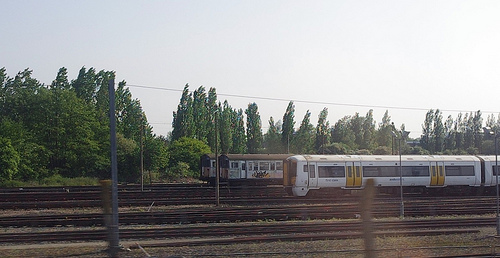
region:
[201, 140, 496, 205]
three trains on the tracks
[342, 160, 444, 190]
yellow doors on the train cars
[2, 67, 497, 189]
trees behind the train tracks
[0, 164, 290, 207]
tracks the trains are on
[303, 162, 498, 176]
windows on the side of white and yellow train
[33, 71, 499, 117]
wire running above the trains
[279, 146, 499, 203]
this is a train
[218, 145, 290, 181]
this is a train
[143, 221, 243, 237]
this is a railway line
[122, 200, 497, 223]
this is a railway line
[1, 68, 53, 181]
this is green vegetation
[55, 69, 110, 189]
this is green vegetation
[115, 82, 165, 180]
this is green vegetation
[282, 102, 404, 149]
this is green vegetation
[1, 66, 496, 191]
The trees lining the track line.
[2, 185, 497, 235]
The tracks the trains are traveling on.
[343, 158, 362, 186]
The first set of yellow doors on the train.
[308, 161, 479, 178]
The passenger windows of the train with the yellow doors.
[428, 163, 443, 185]
The second set of yellow double doors on the train.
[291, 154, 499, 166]
The roof of the train with yellow doors.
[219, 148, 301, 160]
The brown roof of the train in the middle.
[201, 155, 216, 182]
The front of the train on the far left.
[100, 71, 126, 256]
The tall pole in the train yard.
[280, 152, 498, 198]
white train with yellow doors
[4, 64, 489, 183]
trees behind the trains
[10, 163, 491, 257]
several sets of train tracks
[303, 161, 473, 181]
windows on the side of the train car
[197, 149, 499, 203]
three trains on tracks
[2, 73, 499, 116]
power line running above the train tracks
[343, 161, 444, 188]
double doors on the train car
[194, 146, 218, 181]
train car in the background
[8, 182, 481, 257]
gravel around the train tracks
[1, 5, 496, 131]
blue and white sky above the trees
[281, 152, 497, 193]
a white train with yellow doors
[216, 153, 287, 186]
a white train with yellow doors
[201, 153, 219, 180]
a white train with yellow doors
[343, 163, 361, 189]
yellow doors of a train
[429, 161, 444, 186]
yellow doors of a train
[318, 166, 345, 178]
a train's passenger window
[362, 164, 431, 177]
a train's passenger window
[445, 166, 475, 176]
a train's passenger window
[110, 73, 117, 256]
a grey metal pole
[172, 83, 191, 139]
top of a large pine tree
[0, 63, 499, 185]
the trees are tall and green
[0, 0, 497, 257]
the sky above the train tracks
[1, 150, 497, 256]
the trains and the tracks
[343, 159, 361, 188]
the doors are white and yellow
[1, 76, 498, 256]
the power lines above the tracks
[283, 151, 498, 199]
the train is white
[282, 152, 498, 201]
the yellow doors on the white train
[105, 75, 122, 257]
the pole is gray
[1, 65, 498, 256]
the trees behind the tracks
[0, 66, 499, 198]
the tall trees next to the trains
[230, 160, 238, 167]
window of a train